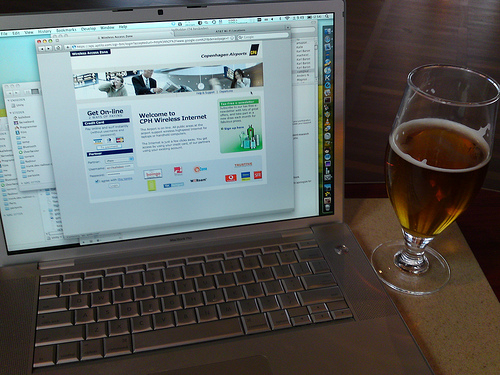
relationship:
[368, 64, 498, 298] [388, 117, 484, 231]
goblet of beer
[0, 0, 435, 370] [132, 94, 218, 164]
laptop with news article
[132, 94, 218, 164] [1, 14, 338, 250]
news article on monitor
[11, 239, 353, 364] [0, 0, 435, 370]
keyboard on laptop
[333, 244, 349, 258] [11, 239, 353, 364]
button to right of keyboard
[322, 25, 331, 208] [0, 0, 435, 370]
task bar on laptop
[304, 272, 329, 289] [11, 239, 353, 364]
enter key on keyboard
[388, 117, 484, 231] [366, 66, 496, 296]
beer in glass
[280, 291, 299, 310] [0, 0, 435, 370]
key on laptop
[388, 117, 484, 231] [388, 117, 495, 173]
beer has foam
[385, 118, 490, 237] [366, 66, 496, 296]
beer in glass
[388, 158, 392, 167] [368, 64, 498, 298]
marking on goblet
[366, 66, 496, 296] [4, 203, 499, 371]
glass on desk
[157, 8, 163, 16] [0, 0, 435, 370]
camera on laptop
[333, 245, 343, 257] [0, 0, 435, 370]
button on laptop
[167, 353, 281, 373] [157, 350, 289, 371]
pad on laptop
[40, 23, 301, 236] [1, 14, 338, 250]
window on monitor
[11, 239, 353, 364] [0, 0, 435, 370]
keyboard of laptop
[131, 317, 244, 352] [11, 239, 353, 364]
bar key on keyboard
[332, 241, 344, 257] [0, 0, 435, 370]
button on laptop